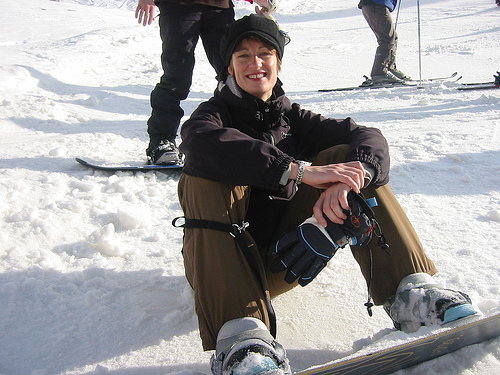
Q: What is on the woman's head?
A: Hat.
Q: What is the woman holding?
A: Gloves.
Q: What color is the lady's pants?
A: Black.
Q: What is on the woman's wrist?
A: Watch.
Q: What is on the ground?
A: Snow.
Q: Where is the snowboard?
A: On the woman's feet.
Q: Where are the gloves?
A: In the woman's hand.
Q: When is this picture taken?
A: During winter.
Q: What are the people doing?
A: Snowboarding.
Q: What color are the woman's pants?
A: Brown.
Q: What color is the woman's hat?
A: Black.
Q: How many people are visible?
A: 3.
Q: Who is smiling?
A: The woman.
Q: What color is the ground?
A: White.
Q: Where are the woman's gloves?
A: In her hand.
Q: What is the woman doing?
A: Sitting.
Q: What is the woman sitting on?
A: Snow.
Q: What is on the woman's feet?
A: Snowboard.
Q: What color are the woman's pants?
A: Brown.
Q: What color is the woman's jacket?
A: Black.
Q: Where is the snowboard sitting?
A: In snow.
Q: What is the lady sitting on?
A: Snow.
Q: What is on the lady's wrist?
A: Bracelet.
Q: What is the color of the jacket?
A: Black.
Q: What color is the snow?
A: White.